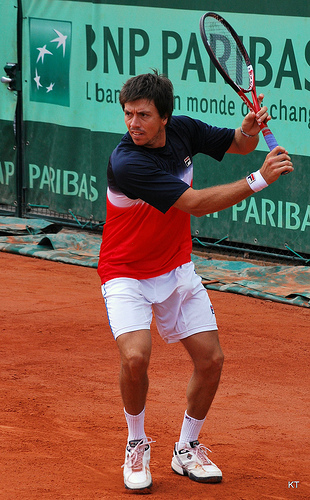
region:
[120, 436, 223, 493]
Men's white tennis shoes with black accents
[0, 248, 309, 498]
Orange clay tennis court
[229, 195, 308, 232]
The word PARIBA in light green letters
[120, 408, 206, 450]
Mid calf men's white socks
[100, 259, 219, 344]
Men's white athletic shorts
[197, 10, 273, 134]
Red and black tennis racquet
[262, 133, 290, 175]
Blue handle of a tennis racquet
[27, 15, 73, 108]
Green sign with white stars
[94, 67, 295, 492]
Man playing tennis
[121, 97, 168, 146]
Man's concentrated face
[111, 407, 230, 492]
white tennis shoes and socks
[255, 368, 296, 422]
clay on the tennis court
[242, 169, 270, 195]
white wrist band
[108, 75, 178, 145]
head of the man playing tennis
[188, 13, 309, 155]
red and blue tennis racket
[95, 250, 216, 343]
white shorts on the man playing tennis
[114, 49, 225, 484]
man playing tennis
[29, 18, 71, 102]
green and white design on sign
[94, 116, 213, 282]
red white and blue shirt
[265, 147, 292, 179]
hand holding tennis racket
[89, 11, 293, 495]
A man is playing tennis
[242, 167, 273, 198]
White armband around man's wrist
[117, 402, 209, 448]
A pair of white socks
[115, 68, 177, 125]
The man has black hair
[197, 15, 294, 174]
Tennis racket in man's hands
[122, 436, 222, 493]
A pair of white sneakers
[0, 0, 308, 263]
A green advertisement sign on the wall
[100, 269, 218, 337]
Player is wearing white shorts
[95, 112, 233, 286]
A red, white and blue shirt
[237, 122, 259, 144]
Watch around the man's wrist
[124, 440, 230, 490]
the shoes are white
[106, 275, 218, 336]
the short is white with ared stripe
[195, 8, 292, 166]
the racket has red,black and blue colours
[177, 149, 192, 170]
the shirt has a logo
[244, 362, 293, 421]
the floor is brownish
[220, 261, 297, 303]
the mat is on background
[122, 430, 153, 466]
the shooe is tied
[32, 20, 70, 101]
white pictures on the wall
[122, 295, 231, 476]
his legs are bent on the knees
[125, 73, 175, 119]
the hair is neatly kept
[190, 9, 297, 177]
the tennis racket in the man's hand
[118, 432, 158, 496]
the man's right foot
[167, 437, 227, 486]
the man's left foot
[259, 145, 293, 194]
the man's right hand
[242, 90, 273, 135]
the man's left hand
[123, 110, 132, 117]
the man's right eye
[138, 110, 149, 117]
the man's left eye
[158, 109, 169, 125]
the man's left ear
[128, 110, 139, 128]
the nose on the man's face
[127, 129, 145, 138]
the mouth on the man's face